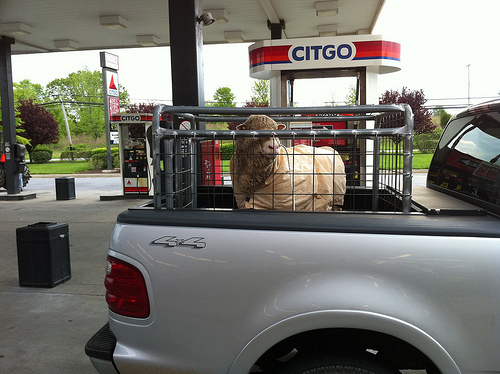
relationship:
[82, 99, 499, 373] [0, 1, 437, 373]
pickup inside of gas station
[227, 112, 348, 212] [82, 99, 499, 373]
sheep inside of pickup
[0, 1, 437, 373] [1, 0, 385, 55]
gas station has roof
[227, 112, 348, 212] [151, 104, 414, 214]
sheep inside of cage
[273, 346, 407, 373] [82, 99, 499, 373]
wheel at back of pickup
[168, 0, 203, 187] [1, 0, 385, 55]
column under roof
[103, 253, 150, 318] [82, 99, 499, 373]
taillight at back of pickup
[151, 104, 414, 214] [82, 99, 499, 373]
cage at back of pickup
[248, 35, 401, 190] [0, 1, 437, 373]
gas pump inside of gas station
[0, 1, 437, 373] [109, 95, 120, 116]
gas station has price sign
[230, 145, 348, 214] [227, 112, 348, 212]
blanket over sheep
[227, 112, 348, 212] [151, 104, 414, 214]
sheep looking out cage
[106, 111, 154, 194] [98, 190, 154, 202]
gas pump on top of island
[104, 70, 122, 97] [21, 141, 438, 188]
sign along side of road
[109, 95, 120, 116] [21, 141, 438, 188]
sign along side of road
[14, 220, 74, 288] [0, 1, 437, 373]
trash can at center of gas station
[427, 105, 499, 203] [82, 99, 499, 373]
window at back of pickup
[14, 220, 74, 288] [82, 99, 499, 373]
trash can behind pickup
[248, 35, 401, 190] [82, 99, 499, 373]
gas pump beside pickup